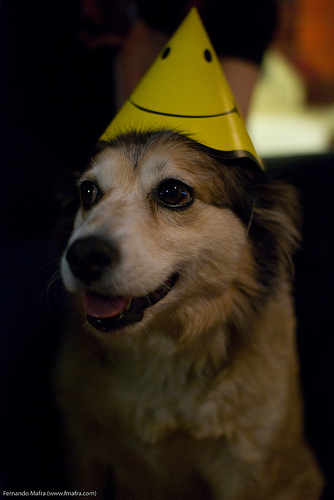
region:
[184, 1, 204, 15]
tip of yellow hat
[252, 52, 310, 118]
white object in the background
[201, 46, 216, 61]
black spot on yellow hat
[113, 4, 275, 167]
yellow hat with black spots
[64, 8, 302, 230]
yellow hat on dog's head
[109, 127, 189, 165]
fur on dog's head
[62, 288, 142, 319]
pink tongue in dog's head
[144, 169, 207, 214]
dog's clear sparkling eyes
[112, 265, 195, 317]
small whiskers on dog's face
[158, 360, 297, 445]
brown and white fur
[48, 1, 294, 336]
A dog wearing a hat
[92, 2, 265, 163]
The hat is yellow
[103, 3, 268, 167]
The hat has a smiley face on it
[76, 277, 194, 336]
Dog's tongue is sticking out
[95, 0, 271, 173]
The hat is in shape of a cone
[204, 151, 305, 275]
Dog's fur is black and yellow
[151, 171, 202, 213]
Dog's eye is black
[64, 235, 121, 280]
The dog's nose is black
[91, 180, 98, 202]
A white portion of dog's eye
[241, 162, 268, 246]
A thin white band attached to the hat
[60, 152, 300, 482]
this is a dog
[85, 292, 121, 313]
this is the dog's tongue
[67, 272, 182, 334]
this is the dog's mouth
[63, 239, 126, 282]
this is the dog's nose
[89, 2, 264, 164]
this is a hat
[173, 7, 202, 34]
the hat is pointed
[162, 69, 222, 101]
the hat is yellow in color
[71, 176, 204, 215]
the eyes are big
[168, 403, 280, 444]
the fur is brown in color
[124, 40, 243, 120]
this is a smiley face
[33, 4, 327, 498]
a dog with a party hat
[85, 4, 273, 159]
a yellow party hat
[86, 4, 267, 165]
hat is a yellow face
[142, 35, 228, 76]
eyes of a yellow face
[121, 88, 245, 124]
mouth of yellow face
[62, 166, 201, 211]
eyes of dog are big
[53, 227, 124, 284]
nose of dog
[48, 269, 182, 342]
mouth of dog is open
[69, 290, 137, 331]
pink mouth of dog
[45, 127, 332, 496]
dog is color brown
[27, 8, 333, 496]
a happy dog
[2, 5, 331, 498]
a puppy looking off in the distance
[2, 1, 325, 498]
a dog wearing a party hat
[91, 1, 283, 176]
a yellow party hat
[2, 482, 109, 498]
a watermark on a lower left corner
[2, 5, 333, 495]
a dark area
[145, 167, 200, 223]
a black eye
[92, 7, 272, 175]
a smiley face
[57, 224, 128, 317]
a black nose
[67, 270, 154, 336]
a pink tongue